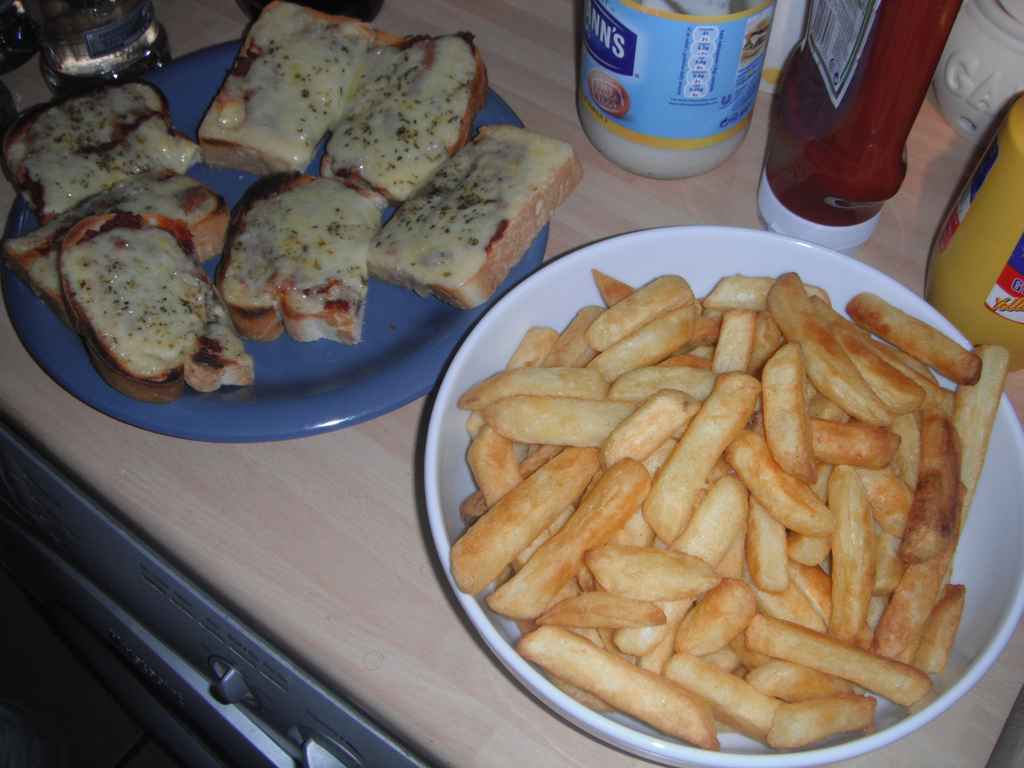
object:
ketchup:
[758, 0, 963, 250]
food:
[6, 7, 1011, 766]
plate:
[5, 0, 1024, 768]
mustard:
[923, 61, 1022, 376]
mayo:
[570, 0, 765, 181]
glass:
[43, 0, 169, 87]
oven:
[0, 414, 413, 766]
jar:
[929, 0, 1024, 145]